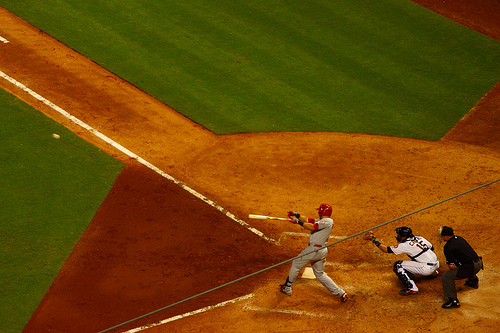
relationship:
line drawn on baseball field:
[203, 190, 278, 249] [0, 0, 466, 325]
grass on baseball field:
[0, 147, 53, 259] [0, 0, 466, 325]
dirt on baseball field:
[106, 109, 147, 138] [0, 0, 466, 325]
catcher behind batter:
[362, 226, 441, 298] [271, 201, 351, 304]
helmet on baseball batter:
[307, 197, 333, 218] [271, 198, 361, 309]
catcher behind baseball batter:
[362, 214, 442, 302] [278, 202, 349, 301]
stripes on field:
[21, 80, 164, 177] [10, 10, 246, 226]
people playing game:
[276, 208, 483, 311] [103, 70, 486, 321]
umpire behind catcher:
[435, 220, 488, 308] [364, 216, 437, 294]